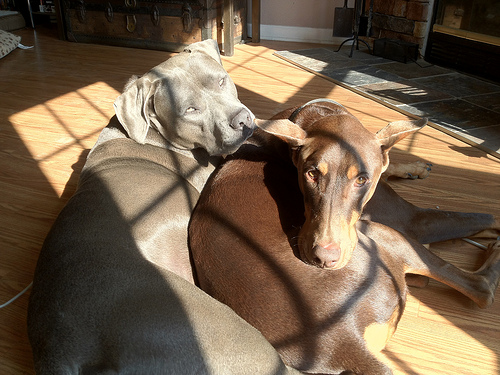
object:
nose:
[314, 247, 340, 266]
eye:
[183, 103, 196, 112]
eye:
[216, 73, 227, 90]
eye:
[305, 167, 323, 187]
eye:
[350, 173, 372, 191]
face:
[294, 149, 377, 267]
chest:
[61, 1, 243, 56]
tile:
[289, 46, 351, 70]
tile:
[324, 68, 401, 86]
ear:
[376, 118, 430, 145]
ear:
[255, 120, 312, 152]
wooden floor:
[0, 44, 499, 374]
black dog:
[27, 35, 292, 373]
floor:
[6, 26, 498, 373]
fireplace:
[408, 4, 498, 86]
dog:
[192, 96, 499, 373]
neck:
[96, 115, 137, 143]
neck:
[285, 95, 344, 115]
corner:
[352, 1, 497, 93]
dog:
[27, 37, 302, 372]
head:
[285, 118, 390, 265]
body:
[188, 142, 403, 371]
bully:
[24, 33, 280, 373]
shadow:
[313, 45, 455, 135]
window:
[244, 27, 480, 172]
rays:
[18, 96, 103, 132]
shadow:
[12, 92, 131, 287]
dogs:
[24, 33, 498, 373]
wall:
[359, 3, 425, 51]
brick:
[414, 20, 428, 35]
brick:
[374, 11, 413, 34]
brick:
[391, 2, 406, 16]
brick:
[370, 0, 395, 15]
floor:
[382, 290, 498, 374]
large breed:
[36, 42, 285, 374]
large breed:
[187, 93, 444, 369]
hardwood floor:
[19, 39, 100, 161]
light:
[77, 74, 255, 337]